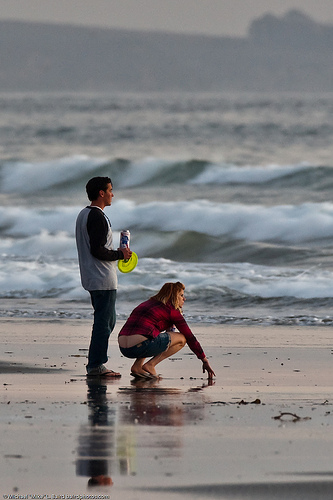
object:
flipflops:
[143, 370, 163, 381]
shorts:
[118, 330, 172, 359]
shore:
[1, 297, 331, 498]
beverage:
[119, 228, 131, 249]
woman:
[117, 281, 218, 380]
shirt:
[74, 205, 125, 294]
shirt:
[117, 292, 206, 362]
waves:
[128, 155, 328, 195]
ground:
[0, 270, 333, 500]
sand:
[259, 384, 332, 498]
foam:
[197, 258, 326, 301]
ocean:
[0, 89, 333, 325]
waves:
[0, 200, 332, 236]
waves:
[0, 229, 190, 257]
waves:
[1, 254, 332, 297]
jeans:
[82, 283, 119, 369]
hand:
[122, 247, 134, 262]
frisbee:
[117, 248, 139, 275]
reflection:
[77, 372, 205, 489]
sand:
[1, 294, 40, 461]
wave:
[0, 120, 333, 143]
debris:
[273, 406, 301, 422]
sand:
[187, 404, 328, 459]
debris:
[311, 398, 330, 407]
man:
[70, 174, 132, 378]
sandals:
[86, 366, 121, 377]